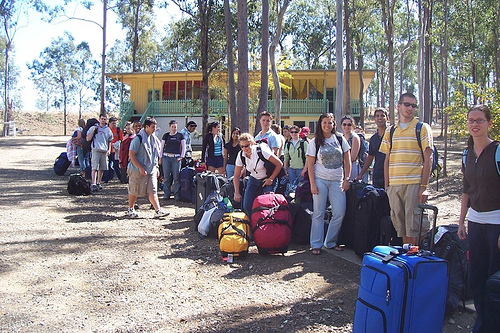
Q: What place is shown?
A: It is a road.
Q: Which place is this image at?
A: It is at the road.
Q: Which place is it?
A: It is a road.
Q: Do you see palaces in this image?
A: No, there are no palaces.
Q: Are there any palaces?
A: No, there are no palaces.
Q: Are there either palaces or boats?
A: No, there are no palaces or boats.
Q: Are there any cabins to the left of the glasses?
A: Yes, there is a cabin to the left of the glasses.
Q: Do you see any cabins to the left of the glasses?
A: Yes, there is a cabin to the left of the glasses.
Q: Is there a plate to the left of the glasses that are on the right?
A: No, there is a cabin to the left of the glasses.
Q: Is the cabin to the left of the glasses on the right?
A: Yes, the cabin is to the left of the glasses.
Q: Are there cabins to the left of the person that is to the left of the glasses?
A: Yes, there is a cabin to the left of the person.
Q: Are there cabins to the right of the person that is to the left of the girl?
A: No, the cabin is to the left of the person.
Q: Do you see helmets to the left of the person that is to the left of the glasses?
A: No, there is a cabin to the left of the person.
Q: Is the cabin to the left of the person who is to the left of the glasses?
A: Yes, the cabin is to the left of the person.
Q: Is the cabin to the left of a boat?
A: No, the cabin is to the left of the person.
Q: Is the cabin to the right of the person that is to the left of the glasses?
A: No, the cabin is to the left of the person.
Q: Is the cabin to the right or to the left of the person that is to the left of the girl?
A: The cabin is to the left of the person.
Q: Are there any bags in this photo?
A: Yes, there is a bag.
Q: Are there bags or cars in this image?
A: Yes, there is a bag.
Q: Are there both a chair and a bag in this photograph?
A: No, there is a bag but no chairs.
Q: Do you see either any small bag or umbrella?
A: Yes, there is a small bag.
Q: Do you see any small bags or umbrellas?
A: Yes, there is a small bag.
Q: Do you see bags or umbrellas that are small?
A: Yes, the bag is small.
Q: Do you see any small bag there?
A: Yes, there is a small bag.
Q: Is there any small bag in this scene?
A: Yes, there is a small bag.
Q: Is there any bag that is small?
A: Yes, there is a bag that is small.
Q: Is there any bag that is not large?
A: Yes, there is a small bag.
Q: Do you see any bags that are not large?
A: Yes, there is a small bag.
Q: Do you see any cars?
A: No, there are no cars.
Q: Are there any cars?
A: No, there are no cars.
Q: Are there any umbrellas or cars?
A: No, there are no cars or umbrellas.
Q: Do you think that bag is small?
A: Yes, the bag is small.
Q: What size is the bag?
A: The bag is small.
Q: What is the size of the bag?
A: The bag is small.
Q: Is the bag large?
A: No, the bag is small.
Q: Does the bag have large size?
A: No, the bag is small.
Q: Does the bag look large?
A: No, the bag is small.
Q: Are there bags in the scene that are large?
A: No, there is a bag but it is small.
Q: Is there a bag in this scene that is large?
A: No, there is a bag but it is small.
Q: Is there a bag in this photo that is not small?
A: No, there is a bag but it is small.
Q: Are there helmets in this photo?
A: No, there are no helmets.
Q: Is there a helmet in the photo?
A: No, there are no helmets.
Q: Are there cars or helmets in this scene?
A: No, there are no helmets or cars.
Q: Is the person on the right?
A: Yes, the person is on the right of the image.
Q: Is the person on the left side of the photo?
A: No, the person is on the right of the image.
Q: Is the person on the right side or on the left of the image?
A: The person is on the right of the image.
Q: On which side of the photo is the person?
A: The person is on the right of the image.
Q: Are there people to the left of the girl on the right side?
A: Yes, there is a person to the left of the girl.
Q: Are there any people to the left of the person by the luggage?
A: Yes, there is a person to the left of the girl.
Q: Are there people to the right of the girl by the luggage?
A: No, the person is to the left of the girl.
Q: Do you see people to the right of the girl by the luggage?
A: No, the person is to the left of the girl.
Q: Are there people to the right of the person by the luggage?
A: No, the person is to the left of the girl.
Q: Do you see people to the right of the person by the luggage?
A: No, the person is to the left of the girl.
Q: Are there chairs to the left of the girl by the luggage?
A: No, there is a person to the left of the girl.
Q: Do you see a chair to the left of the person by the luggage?
A: No, there is a person to the left of the girl.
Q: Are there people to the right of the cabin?
A: Yes, there is a person to the right of the cabin.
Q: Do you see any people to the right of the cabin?
A: Yes, there is a person to the right of the cabin.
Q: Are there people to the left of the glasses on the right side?
A: Yes, there is a person to the left of the glasses.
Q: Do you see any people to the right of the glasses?
A: No, the person is to the left of the glasses.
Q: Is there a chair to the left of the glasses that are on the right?
A: No, there is a person to the left of the glasses.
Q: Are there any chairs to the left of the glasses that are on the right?
A: No, there is a person to the left of the glasses.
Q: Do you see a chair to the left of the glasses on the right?
A: No, there is a person to the left of the glasses.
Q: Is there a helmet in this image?
A: No, there are no helmets.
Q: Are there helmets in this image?
A: No, there are no helmets.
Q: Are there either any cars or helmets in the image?
A: No, there are no helmets or cars.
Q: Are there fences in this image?
A: No, there are no fences.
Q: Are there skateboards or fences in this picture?
A: No, there are no fences or skateboards.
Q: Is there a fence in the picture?
A: No, there are no fences.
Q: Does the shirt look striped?
A: Yes, the shirt is striped.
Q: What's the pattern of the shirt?
A: The shirt is striped.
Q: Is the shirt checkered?
A: No, the shirt is striped.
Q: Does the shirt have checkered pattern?
A: No, the shirt is striped.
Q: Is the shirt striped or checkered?
A: The shirt is striped.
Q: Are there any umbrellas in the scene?
A: No, there are no umbrellas.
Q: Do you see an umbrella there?
A: No, there are no umbrellas.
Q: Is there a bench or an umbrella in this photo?
A: No, there are no umbrellas or benches.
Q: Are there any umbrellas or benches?
A: No, there are no umbrellas or benches.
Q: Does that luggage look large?
A: Yes, the luggage is large.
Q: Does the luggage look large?
A: Yes, the luggage is large.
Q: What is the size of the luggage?
A: The luggage is large.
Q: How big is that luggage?
A: The luggage is large.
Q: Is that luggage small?
A: No, the luggage is large.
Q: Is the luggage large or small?
A: The luggage is large.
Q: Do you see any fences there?
A: No, there are no fences.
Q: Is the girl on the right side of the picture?
A: Yes, the girl is on the right of the image.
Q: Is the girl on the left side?
A: No, the girl is on the right of the image.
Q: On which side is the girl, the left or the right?
A: The girl is on the right of the image.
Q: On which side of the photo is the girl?
A: The girl is on the right of the image.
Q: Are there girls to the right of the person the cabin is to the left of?
A: Yes, there is a girl to the right of the person.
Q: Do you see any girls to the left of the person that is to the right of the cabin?
A: No, the girl is to the right of the person.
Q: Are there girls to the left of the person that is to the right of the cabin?
A: No, the girl is to the right of the person.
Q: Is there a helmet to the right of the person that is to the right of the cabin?
A: No, there is a girl to the right of the person.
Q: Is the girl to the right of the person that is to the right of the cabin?
A: Yes, the girl is to the right of the person.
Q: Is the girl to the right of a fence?
A: No, the girl is to the right of the person.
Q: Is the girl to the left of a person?
A: No, the girl is to the right of a person.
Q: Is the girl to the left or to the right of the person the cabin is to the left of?
A: The girl is to the right of the person.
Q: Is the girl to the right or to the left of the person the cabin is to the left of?
A: The girl is to the right of the person.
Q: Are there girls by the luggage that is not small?
A: Yes, there is a girl by the luggage.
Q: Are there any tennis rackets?
A: No, there are no tennis rackets.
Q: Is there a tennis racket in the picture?
A: No, there are no rackets.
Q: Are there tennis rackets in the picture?
A: No, there are no tennis rackets.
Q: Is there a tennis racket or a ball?
A: No, there are no rackets or balls.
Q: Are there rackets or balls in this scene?
A: No, there are no rackets or balls.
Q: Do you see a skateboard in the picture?
A: No, there are no skateboards.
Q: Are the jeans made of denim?
A: Yes, the jeans are made of denim.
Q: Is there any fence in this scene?
A: No, there are no fences.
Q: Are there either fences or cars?
A: No, there are no fences or cars.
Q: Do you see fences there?
A: No, there are no fences.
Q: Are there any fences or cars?
A: No, there are no fences or cars.